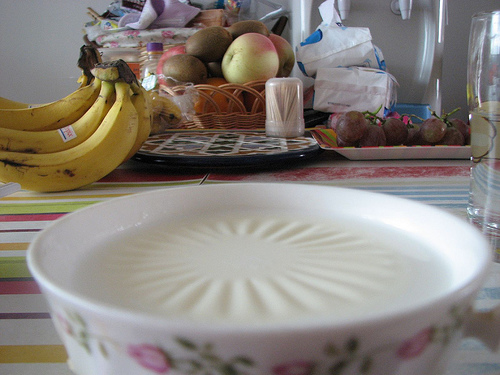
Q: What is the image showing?
A: It is showing a kitchen.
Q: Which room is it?
A: It is a kitchen.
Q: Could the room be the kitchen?
A: Yes, it is the kitchen.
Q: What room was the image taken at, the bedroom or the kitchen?
A: It was taken at the kitchen.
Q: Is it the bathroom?
A: No, it is the kitchen.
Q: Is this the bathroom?
A: No, it is the kitchen.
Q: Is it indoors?
A: Yes, it is indoors.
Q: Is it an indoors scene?
A: Yes, it is indoors.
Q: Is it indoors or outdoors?
A: It is indoors.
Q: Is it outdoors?
A: No, it is indoors.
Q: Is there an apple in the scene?
A: Yes, there is an apple.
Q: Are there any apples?
A: Yes, there is an apple.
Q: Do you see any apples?
A: Yes, there is an apple.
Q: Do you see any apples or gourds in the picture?
A: Yes, there is an apple.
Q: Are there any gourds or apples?
A: Yes, there is an apple.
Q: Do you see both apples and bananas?
A: Yes, there are both an apple and a banana.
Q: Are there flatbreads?
A: No, there are no flatbreads.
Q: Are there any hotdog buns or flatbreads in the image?
A: No, there are no flatbreads or hotdog buns.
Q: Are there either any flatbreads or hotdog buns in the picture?
A: No, there are no flatbreads or hotdog buns.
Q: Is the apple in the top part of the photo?
A: Yes, the apple is in the top of the image.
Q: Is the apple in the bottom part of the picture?
A: No, the apple is in the top of the image.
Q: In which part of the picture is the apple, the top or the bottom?
A: The apple is in the top of the image.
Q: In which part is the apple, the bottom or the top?
A: The apple is in the top of the image.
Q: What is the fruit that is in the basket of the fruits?
A: The fruit is an apple.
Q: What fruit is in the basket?
A: The fruit is an apple.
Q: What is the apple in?
A: The apple is in the basket.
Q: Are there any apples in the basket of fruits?
A: Yes, there is an apple in the basket.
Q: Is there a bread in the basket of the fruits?
A: No, there is an apple in the basket.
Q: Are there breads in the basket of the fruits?
A: No, there is an apple in the basket.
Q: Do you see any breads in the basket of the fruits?
A: No, there is an apple in the basket.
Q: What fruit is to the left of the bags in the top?
A: The fruit is an apple.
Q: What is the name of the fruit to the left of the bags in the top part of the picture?
A: The fruit is an apple.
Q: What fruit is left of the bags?
A: The fruit is an apple.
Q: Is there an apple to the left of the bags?
A: Yes, there is an apple to the left of the bags.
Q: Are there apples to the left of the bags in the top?
A: Yes, there is an apple to the left of the bags.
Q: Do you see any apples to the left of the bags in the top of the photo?
A: Yes, there is an apple to the left of the bags.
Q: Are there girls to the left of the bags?
A: No, there is an apple to the left of the bags.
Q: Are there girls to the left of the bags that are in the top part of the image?
A: No, there is an apple to the left of the bags.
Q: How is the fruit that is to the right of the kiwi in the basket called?
A: The fruit is an apple.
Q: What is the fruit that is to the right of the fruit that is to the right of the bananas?
A: The fruit is an apple.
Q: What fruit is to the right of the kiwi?
A: The fruit is an apple.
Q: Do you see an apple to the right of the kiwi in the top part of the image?
A: Yes, there is an apple to the right of the kiwi.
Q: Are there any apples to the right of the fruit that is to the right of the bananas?
A: Yes, there is an apple to the right of the kiwi.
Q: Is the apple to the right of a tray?
A: No, the apple is to the right of the kiwi.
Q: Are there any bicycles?
A: No, there are no bicycles.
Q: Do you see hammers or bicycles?
A: No, there are no bicycles or hammers.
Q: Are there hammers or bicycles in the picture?
A: No, there are no bicycles or hammers.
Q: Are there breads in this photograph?
A: No, there are no breads.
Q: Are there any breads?
A: No, there are no breads.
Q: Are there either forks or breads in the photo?
A: No, there are no breads or forks.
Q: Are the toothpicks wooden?
A: Yes, the toothpicks are wooden.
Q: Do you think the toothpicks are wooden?
A: Yes, the toothpicks are wooden.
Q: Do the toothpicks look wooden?
A: Yes, the toothpicks are wooden.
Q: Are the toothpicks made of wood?
A: Yes, the toothpicks are made of wood.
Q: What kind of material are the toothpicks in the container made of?
A: The toothpicks are made of wood.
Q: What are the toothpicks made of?
A: The toothpicks are made of wood.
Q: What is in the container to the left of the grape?
A: The toothpicks are in the container.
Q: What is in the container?
A: The toothpicks are in the container.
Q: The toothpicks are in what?
A: The toothpicks are in the container.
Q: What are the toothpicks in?
A: The toothpicks are in the container.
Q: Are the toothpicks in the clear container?
A: Yes, the toothpicks are in the container.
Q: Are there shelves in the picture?
A: No, there are no shelves.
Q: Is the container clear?
A: Yes, the container is clear.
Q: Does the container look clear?
A: Yes, the container is clear.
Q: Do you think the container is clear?
A: Yes, the container is clear.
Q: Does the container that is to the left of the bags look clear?
A: Yes, the container is clear.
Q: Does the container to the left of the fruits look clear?
A: Yes, the container is clear.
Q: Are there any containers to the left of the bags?
A: Yes, there is a container to the left of the bags.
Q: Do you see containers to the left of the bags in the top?
A: Yes, there is a container to the left of the bags.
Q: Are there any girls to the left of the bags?
A: No, there is a container to the left of the bags.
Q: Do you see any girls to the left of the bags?
A: No, there is a container to the left of the bags.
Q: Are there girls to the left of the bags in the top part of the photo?
A: No, there is a container to the left of the bags.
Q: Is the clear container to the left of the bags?
A: Yes, the container is to the left of the bags.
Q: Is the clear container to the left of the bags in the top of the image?
A: Yes, the container is to the left of the bags.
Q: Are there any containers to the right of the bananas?
A: Yes, there is a container to the right of the bananas.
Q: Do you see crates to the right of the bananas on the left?
A: No, there is a container to the right of the bananas.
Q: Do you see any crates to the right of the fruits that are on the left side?
A: No, there is a container to the right of the bananas.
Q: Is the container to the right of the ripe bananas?
A: Yes, the container is to the right of the bananas.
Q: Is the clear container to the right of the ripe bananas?
A: Yes, the container is to the right of the bananas.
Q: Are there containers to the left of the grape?
A: Yes, there is a container to the left of the grape.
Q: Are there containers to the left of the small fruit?
A: Yes, there is a container to the left of the grape.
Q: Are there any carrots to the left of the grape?
A: No, there is a container to the left of the grape.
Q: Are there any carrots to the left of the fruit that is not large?
A: No, there is a container to the left of the grape.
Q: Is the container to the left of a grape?
A: Yes, the container is to the left of a grape.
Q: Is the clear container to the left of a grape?
A: Yes, the container is to the left of a grape.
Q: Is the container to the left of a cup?
A: No, the container is to the left of a grape.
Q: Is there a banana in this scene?
A: Yes, there are bananas.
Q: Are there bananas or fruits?
A: Yes, there are bananas.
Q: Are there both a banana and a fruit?
A: Yes, there are both a banana and a fruit.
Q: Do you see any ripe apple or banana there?
A: Yes, there are ripe bananas.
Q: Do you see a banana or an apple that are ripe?
A: Yes, the bananas are ripe.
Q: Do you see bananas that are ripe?
A: Yes, there are ripe bananas.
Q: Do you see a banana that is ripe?
A: Yes, there are bananas that are ripe.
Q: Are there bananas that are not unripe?
A: Yes, there are ripe bananas.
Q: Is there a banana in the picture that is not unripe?
A: Yes, there are ripe bananas.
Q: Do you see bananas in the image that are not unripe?
A: Yes, there are ripe bananas.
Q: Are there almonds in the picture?
A: No, there are no almonds.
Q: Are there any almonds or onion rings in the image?
A: No, there are no almonds or onion rings.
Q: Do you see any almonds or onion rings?
A: No, there are no almonds or onion rings.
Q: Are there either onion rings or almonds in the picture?
A: No, there are no almonds or onion rings.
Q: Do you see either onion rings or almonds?
A: No, there are no almonds or onion rings.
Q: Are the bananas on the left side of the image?
A: Yes, the bananas are on the left of the image.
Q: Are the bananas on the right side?
A: No, the bananas are on the left of the image.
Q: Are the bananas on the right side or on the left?
A: The bananas are on the left of the image.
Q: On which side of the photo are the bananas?
A: The bananas are on the left of the image.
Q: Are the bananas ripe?
A: Yes, the bananas are ripe.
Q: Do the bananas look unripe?
A: No, the bananas are ripe.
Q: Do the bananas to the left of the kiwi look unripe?
A: No, the bananas are ripe.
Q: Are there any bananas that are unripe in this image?
A: No, there are bananas but they are ripe.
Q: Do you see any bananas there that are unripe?
A: No, there are bananas but they are ripe.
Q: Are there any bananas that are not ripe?
A: No, there are bananas but they are ripe.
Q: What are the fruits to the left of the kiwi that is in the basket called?
A: The fruits are bananas.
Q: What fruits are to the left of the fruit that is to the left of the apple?
A: The fruits are bananas.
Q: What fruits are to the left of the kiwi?
A: The fruits are bananas.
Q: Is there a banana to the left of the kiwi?
A: Yes, there are bananas to the left of the kiwi.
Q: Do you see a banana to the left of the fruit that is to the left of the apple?
A: Yes, there are bananas to the left of the kiwi.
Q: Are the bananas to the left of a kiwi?
A: Yes, the bananas are to the left of a kiwi.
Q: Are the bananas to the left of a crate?
A: No, the bananas are to the left of a kiwi.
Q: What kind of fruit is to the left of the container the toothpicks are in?
A: The fruits are bananas.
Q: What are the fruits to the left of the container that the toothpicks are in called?
A: The fruits are bananas.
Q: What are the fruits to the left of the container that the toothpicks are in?
A: The fruits are bananas.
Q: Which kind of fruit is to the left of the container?
A: The fruits are bananas.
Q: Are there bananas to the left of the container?
A: Yes, there are bananas to the left of the container.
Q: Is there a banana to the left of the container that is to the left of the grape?
A: Yes, there are bananas to the left of the container.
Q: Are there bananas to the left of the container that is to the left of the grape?
A: Yes, there are bananas to the left of the container.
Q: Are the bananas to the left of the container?
A: Yes, the bananas are to the left of the container.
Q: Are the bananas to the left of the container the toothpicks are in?
A: Yes, the bananas are to the left of the container.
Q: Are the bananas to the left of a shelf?
A: No, the bananas are to the left of the container.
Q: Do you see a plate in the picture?
A: Yes, there is a plate.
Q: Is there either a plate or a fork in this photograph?
A: Yes, there is a plate.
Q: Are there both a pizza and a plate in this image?
A: No, there is a plate but no pizzas.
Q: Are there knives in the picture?
A: No, there are no knives.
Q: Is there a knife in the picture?
A: No, there are no knives.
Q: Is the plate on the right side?
A: Yes, the plate is on the right of the image.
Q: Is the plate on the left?
A: No, the plate is on the right of the image.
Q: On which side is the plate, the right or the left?
A: The plate is on the right of the image.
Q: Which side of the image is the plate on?
A: The plate is on the right of the image.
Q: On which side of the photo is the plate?
A: The plate is on the right of the image.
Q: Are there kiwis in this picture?
A: Yes, there is a kiwi.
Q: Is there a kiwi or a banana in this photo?
A: Yes, there is a kiwi.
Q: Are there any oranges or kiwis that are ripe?
A: Yes, the kiwi is ripe.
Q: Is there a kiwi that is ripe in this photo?
A: Yes, there is a ripe kiwi.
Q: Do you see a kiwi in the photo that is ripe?
A: Yes, there is a kiwi that is ripe.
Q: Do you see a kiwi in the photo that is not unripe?
A: Yes, there is an ripe kiwi.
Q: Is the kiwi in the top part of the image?
A: Yes, the kiwi is in the top of the image.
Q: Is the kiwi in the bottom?
A: No, the kiwi is in the top of the image.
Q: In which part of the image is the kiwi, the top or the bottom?
A: The kiwi is in the top of the image.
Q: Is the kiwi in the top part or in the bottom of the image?
A: The kiwi is in the top of the image.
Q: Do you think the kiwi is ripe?
A: Yes, the kiwi is ripe.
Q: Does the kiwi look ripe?
A: Yes, the kiwi is ripe.